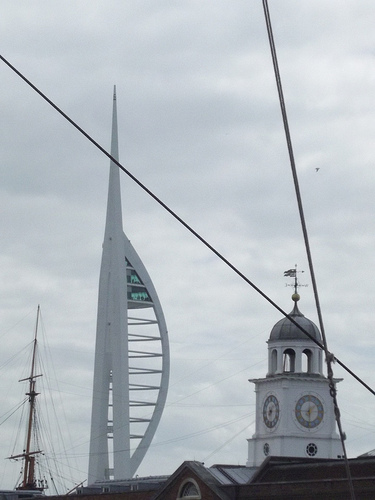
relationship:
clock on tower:
[291, 390, 327, 430] [237, 255, 349, 466]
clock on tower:
[257, 390, 283, 433] [237, 255, 349, 466]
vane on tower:
[281, 260, 310, 298] [237, 255, 349, 466]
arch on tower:
[279, 347, 298, 374] [237, 255, 349, 466]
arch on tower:
[296, 345, 317, 376] [237, 255, 349, 466]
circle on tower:
[302, 439, 319, 458] [237, 255, 349, 466]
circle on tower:
[259, 440, 271, 458] [237, 255, 349, 466]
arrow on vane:
[287, 279, 310, 291] [281, 260, 310, 298]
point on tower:
[291, 261, 299, 272] [237, 255, 349, 466]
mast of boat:
[9, 300, 48, 487] [0, 451, 47, 499]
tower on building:
[237, 255, 349, 466] [30, 443, 374, 500]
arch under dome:
[279, 347, 298, 374] [262, 311, 322, 351]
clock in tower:
[291, 390, 327, 430] [237, 255, 349, 466]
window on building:
[174, 478, 201, 499] [30, 443, 374, 500]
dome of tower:
[262, 311, 322, 351] [237, 255, 349, 466]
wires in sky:
[1, 54, 374, 393] [1, 2, 373, 497]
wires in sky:
[257, 3, 360, 500] [1, 2, 373, 497]